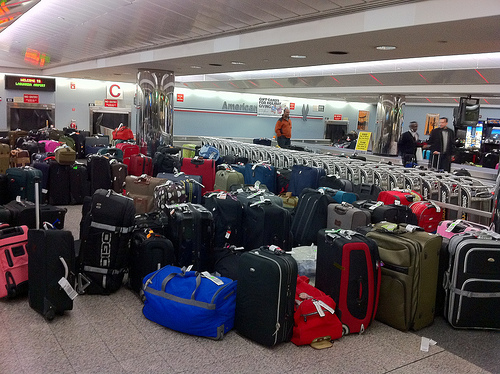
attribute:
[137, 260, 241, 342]
luggage — black, blue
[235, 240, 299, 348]
luggage — black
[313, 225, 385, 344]
luggage — red, black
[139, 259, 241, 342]
duffel — blue, gray, laying down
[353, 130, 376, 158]
sign — yellow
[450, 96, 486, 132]
monitor — hanging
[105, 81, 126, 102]
sign — white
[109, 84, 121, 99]
letter — red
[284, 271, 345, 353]
bag — large, red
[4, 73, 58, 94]
sign — black, rectangular, electronic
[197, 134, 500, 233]
carts — silver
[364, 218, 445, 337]
suitcase — large, olive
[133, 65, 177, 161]
pole — large, silver, shiny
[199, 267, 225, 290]
tag — white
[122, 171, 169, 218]
luggage — brown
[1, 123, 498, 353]
group — large, luggage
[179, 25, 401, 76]
lights — row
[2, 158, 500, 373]
floor — gray, tiled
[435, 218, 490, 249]
bag — pink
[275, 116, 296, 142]
coat — orange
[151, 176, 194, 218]
bag — dotted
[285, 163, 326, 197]
bag — dark blue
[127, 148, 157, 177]
bag — maroon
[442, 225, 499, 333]
suitcase — black, gray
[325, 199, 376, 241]
suitcase — gray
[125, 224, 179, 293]
bag — black